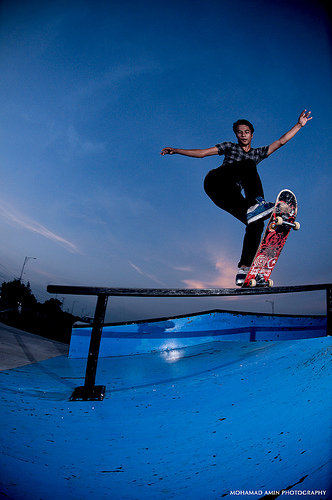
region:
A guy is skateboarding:
[157, 104, 315, 292]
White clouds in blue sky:
[1, 0, 329, 319]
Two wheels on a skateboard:
[270, 208, 303, 231]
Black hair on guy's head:
[230, 114, 260, 148]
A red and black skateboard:
[240, 186, 301, 290]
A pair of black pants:
[204, 155, 267, 268]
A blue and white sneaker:
[240, 194, 276, 224]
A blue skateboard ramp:
[1, 307, 330, 497]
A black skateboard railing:
[41, 279, 330, 401]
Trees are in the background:
[1, 275, 80, 347]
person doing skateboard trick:
[166, 93, 322, 287]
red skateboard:
[261, 184, 301, 292]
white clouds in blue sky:
[16, 22, 57, 57]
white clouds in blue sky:
[54, 97, 105, 150]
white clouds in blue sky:
[18, 117, 53, 179]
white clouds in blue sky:
[13, 202, 57, 253]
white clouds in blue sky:
[167, 248, 217, 274]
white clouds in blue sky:
[185, 238, 232, 283]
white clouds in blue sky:
[146, 28, 201, 76]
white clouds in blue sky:
[242, 15, 288, 62]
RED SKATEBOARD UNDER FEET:
[228, 183, 308, 285]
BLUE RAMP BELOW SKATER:
[72, 280, 322, 490]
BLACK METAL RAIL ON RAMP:
[26, 274, 321, 366]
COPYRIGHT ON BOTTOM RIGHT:
[209, 471, 328, 495]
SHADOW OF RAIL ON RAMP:
[72, 297, 273, 355]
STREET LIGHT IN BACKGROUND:
[9, 254, 61, 292]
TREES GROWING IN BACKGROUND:
[0, 277, 82, 330]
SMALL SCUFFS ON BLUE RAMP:
[175, 366, 256, 439]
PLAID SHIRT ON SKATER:
[200, 130, 252, 175]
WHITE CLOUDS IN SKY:
[55, 182, 213, 309]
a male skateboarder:
[157, 108, 313, 291]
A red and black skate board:
[241, 188, 299, 288]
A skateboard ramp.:
[0, 309, 330, 498]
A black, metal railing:
[46, 279, 331, 399]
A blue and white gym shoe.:
[246, 195, 275, 224]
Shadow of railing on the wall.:
[71, 323, 326, 337]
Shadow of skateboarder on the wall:
[133, 318, 175, 332]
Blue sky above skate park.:
[0, 0, 331, 324]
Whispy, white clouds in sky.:
[0, 197, 84, 254]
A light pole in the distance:
[17, 255, 36, 284]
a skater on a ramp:
[36, 94, 329, 408]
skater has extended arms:
[152, 99, 319, 208]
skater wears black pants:
[148, 97, 322, 305]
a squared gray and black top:
[214, 140, 271, 169]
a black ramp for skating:
[29, 278, 330, 417]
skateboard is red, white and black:
[240, 183, 301, 294]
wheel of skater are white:
[248, 215, 303, 289]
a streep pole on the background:
[18, 242, 40, 293]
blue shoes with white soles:
[224, 200, 276, 291]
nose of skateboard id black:
[274, 181, 304, 217]